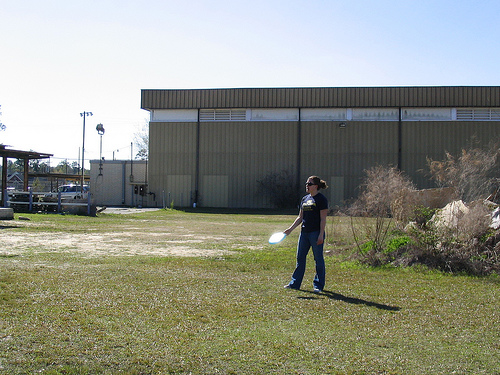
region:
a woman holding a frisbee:
[267, 174, 329, 294]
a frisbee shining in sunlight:
[266, 229, 287, 244]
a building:
[87, 84, 498, 219]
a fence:
[5, 188, 92, 216]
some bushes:
[331, 147, 499, 277]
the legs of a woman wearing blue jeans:
[281, 227, 326, 294]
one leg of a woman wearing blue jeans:
[306, 227, 327, 294]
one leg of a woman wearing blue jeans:
[281, 231, 312, 291]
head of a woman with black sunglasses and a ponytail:
[304, 174, 329, 194]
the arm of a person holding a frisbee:
[267, 205, 303, 245]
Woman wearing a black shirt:
[272, 173, 336, 298]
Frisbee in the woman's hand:
[261, 221, 291, 248]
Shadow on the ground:
[292, 271, 405, 324]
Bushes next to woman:
[327, 146, 498, 290]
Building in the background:
[122, 71, 493, 233]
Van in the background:
[33, 176, 96, 203]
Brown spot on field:
[0, 218, 250, 275]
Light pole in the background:
[70, 101, 99, 191]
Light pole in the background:
[89, 115, 121, 172]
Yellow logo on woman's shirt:
[300, 193, 324, 215]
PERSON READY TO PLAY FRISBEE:
[265, 171, 331, 297]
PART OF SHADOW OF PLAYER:
[339, 288, 384, 320]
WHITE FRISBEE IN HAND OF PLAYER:
[264, 225, 286, 247]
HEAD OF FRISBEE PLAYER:
[298, 175, 331, 198]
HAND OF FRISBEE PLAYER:
[281, 224, 291, 236]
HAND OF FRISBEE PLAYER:
[313, 229, 325, 241]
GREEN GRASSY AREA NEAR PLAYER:
[202, 286, 252, 324]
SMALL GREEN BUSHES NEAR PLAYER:
[391, 235, 406, 251]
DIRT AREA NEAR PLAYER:
[71, 240, 123, 254]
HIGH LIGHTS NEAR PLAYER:
[71, 106, 98, 119]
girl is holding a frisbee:
[265, 227, 290, 249]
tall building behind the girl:
[139, 72, 446, 209]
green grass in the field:
[91, 296, 301, 373]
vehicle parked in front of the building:
[50, 179, 91, 199]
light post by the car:
[71, 102, 101, 172]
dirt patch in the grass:
[11, 234, 186, 266]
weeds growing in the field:
[351, 162, 438, 281]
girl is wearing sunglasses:
[301, 170, 321, 192]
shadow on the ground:
[329, 275, 404, 324]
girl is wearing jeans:
[291, 227, 331, 296]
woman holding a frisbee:
[258, 169, 344, 302]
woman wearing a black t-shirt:
[266, 168, 341, 298]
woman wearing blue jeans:
[256, 172, 343, 303]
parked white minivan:
[39, 182, 91, 205]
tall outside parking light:
[79, 103, 99, 198]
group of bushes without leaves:
[340, 145, 492, 300]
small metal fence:
[7, 185, 98, 220]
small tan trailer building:
[85, 150, 150, 215]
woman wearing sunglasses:
[267, 178, 342, 303]